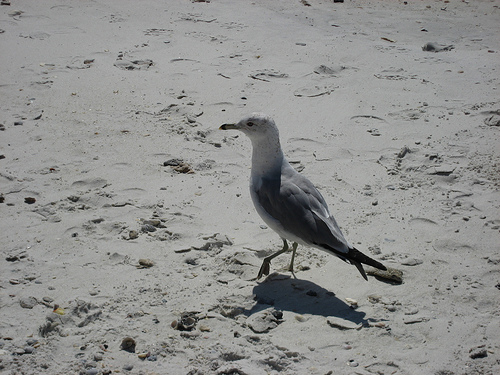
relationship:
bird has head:
[217, 112, 391, 284] [215, 108, 285, 149]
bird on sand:
[189, 56, 394, 337] [348, 72, 466, 152]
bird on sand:
[217, 112, 391, 284] [1, 1, 498, 372]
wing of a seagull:
[256, 178, 342, 253] [188, 104, 440, 348]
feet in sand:
[252, 233, 317, 283] [189, 257, 340, 336]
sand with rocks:
[56, 200, 153, 310] [16, 263, 170, 373]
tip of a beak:
[219, 121, 234, 133] [218, 123, 241, 129]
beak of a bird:
[217, 121, 240, 132] [217, 112, 391, 284]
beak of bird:
[219, 121, 239, 132] [218, 110, 387, 285]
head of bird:
[218, 113, 280, 145] [218, 110, 387, 285]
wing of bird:
[256, 178, 351, 260] [218, 110, 387, 285]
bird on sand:
[217, 112, 391, 284] [174, 156, 283, 282]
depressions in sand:
[2, 39, 495, 374] [1, 1, 498, 372]